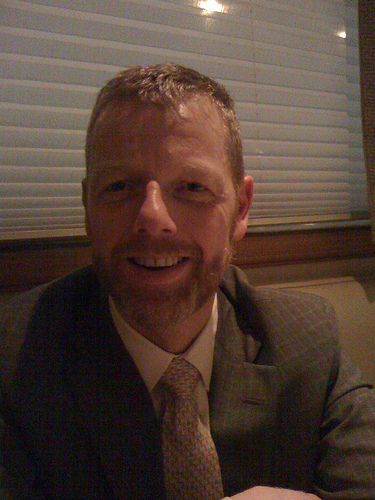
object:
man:
[1, 62, 374, 498]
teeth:
[128, 253, 187, 271]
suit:
[0, 261, 372, 500]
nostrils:
[133, 223, 173, 241]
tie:
[156, 356, 222, 500]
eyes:
[101, 175, 207, 195]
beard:
[86, 246, 231, 327]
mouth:
[124, 251, 192, 279]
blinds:
[0, 0, 369, 240]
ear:
[231, 174, 255, 242]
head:
[84, 60, 246, 326]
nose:
[132, 177, 178, 237]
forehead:
[86, 94, 225, 173]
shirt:
[106, 286, 219, 444]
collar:
[104, 289, 219, 390]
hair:
[85, 59, 246, 185]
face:
[87, 92, 237, 324]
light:
[192, 0, 347, 41]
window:
[0, 0, 373, 241]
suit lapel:
[242, 400, 304, 460]